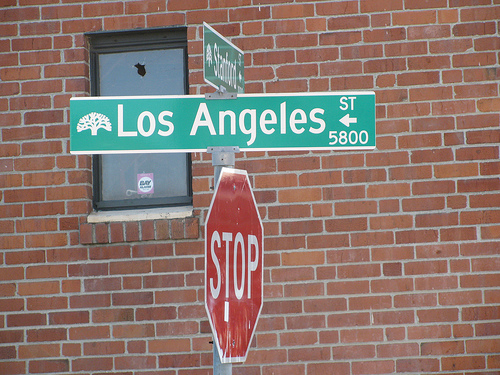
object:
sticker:
[137, 172, 155, 194]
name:
[114, 103, 328, 145]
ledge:
[85, 206, 194, 224]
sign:
[203, 166, 266, 364]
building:
[0, 2, 500, 375]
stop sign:
[204, 166, 264, 363]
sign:
[68, 91, 374, 155]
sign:
[203, 22, 244, 92]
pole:
[212, 94, 232, 375]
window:
[91, 32, 192, 211]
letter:
[116, 103, 137, 137]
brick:
[295, 46, 338, 63]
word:
[210, 230, 259, 300]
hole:
[134, 62, 147, 76]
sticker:
[223, 301, 231, 322]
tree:
[77, 112, 113, 136]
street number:
[328, 130, 368, 144]